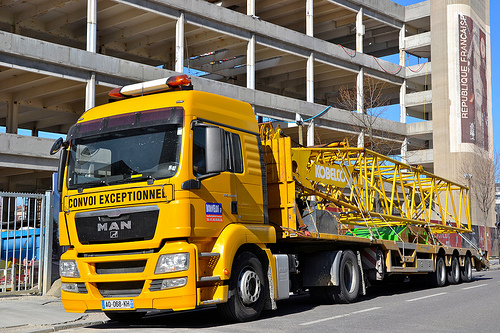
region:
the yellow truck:
[47, 70, 488, 317]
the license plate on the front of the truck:
[97, 298, 134, 312]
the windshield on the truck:
[65, 119, 180, 185]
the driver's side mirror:
[192, 120, 226, 189]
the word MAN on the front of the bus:
[95, 215, 132, 233]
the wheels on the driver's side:
[230, 235, 475, 317]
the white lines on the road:
[291, 274, 484, 331]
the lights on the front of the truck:
[57, 252, 188, 292]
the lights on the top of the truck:
[103, 75, 190, 99]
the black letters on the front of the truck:
[57, 184, 169, 209]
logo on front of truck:
[106, 226, 123, 243]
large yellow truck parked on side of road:
[44, 72, 498, 325]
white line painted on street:
[389, 274, 460, 311]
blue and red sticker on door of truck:
[193, 195, 235, 229]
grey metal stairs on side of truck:
[191, 240, 231, 308]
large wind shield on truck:
[57, 105, 183, 191]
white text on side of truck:
[306, 153, 357, 188]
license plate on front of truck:
[93, 291, 149, 316]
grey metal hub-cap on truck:
[241, 271, 266, 310]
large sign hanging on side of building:
[441, 5, 497, 165]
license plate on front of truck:
[98, 294, 138, 311]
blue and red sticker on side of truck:
[196, 199, 229, 224]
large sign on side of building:
[444, 3, 497, 161]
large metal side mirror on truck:
[191, 118, 229, 190]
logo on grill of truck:
[106, 228, 121, 243]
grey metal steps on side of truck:
[189, 240, 230, 306]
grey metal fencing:
[0, 189, 50, 294]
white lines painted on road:
[301, 300, 391, 330]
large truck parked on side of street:
[41, 73, 497, 317]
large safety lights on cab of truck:
[92, 65, 197, 102]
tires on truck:
[227, 243, 488, 315]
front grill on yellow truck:
[56, 245, 201, 315]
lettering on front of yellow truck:
[65, 182, 176, 210]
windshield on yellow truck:
[62, 108, 186, 190]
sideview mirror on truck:
[44, 131, 71, 163]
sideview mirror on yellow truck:
[176, 116, 228, 193]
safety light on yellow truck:
[98, 73, 208, 103]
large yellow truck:
[48, 74, 476, 321]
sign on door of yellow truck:
[200, 195, 226, 228]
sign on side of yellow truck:
[307, 157, 352, 188]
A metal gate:
[1, 190, 45, 296]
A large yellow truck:
[51, 75, 483, 319]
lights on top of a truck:
[106, 70, 190, 95]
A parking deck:
[3, 1, 495, 228]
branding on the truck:
[88, 215, 138, 237]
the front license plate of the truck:
[101, 298, 137, 309]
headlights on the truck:
[61, 253, 188, 298]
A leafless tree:
[456, 148, 498, 253]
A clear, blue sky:
[0, 0, 498, 202]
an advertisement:
[443, 5, 493, 159]